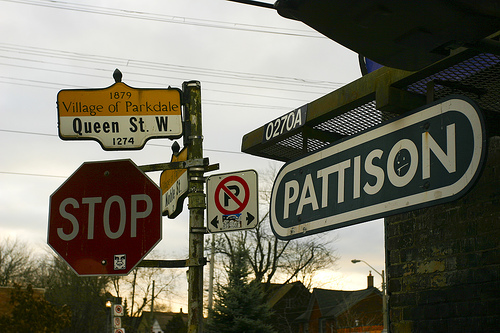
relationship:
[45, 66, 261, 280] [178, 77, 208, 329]
signs on post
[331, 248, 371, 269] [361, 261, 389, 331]
light on pole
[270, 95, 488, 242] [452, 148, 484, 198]
green sign with corners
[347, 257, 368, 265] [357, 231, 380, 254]
light in air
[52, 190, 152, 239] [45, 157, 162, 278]
stop on sign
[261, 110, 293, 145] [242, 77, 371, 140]
numbers on awning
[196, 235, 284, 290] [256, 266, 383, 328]
trees behind houses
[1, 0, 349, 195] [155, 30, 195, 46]
wires in air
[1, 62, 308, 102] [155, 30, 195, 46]
wires in air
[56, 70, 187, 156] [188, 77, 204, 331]
sign on pole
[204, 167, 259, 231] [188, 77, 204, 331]
sign on pole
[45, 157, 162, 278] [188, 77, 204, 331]
sign on pole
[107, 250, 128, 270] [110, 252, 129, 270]
face on sticker